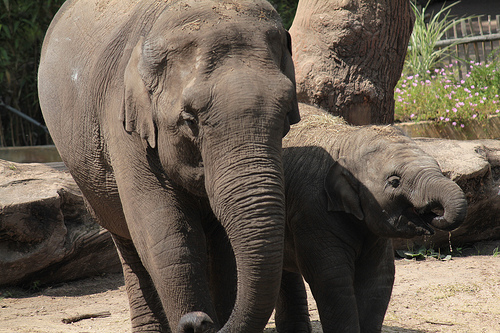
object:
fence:
[406, 14, 498, 82]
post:
[486, 14, 496, 62]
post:
[476, 15, 488, 64]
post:
[458, 17, 471, 75]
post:
[452, 16, 463, 81]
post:
[442, 16, 453, 74]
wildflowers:
[398, 70, 490, 120]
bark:
[368, 38, 391, 65]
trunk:
[178, 135, 287, 333]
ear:
[324, 156, 364, 221]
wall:
[0, 134, 498, 291]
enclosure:
[2, 2, 500, 333]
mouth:
[389, 194, 441, 239]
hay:
[306, 111, 347, 124]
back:
[284, 127, 378, 140]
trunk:
[412, 172, 467, 233]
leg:
[296, 252, 363, 333]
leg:
[351, 244, 395, 333]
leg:
[272, 267, 312, 332]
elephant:
[36, 0, 302, 332]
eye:
[175, 106, 199, 130]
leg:
[104, 159, 224, 333]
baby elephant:
[262, 134, 469, 333]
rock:
[0, 149, 121, 291]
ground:
[0, 248, 500, 333]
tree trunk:
[286, 0, 415, 125]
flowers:
[416, 70, 476, 121]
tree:
[288, 0, 416, 124]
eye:
[281, 109, 293, 135]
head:
[323, 134, 468, 241]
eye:
[386, 175, 400, 189]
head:
[120, 7, 300, 333]